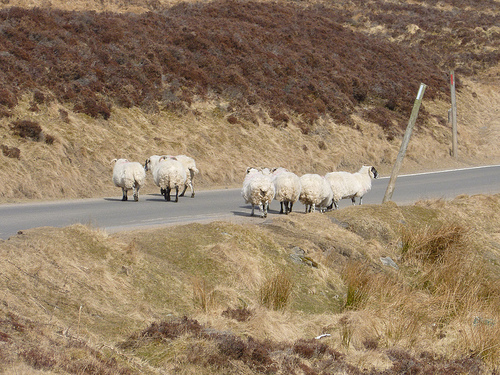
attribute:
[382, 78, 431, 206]
wood pole — crooked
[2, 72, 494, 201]
grass — tan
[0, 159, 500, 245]
road — paved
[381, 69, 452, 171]
pole — gray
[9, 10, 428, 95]
darkbrown grass — dark brown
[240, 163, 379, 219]
sheep — white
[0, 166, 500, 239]
road — paved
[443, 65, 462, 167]
pole — metal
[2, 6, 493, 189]
grass — dry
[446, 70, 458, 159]
post — wooden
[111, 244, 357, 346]
grass — dry, grassy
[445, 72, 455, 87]
paint — red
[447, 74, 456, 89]
sticker — red